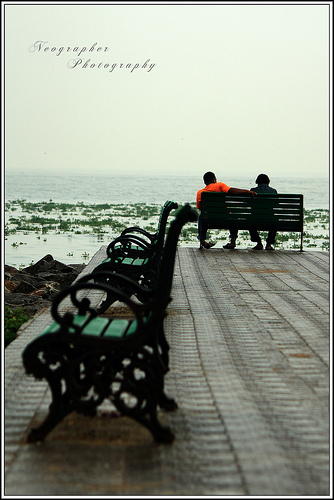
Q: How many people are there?
A: Two.